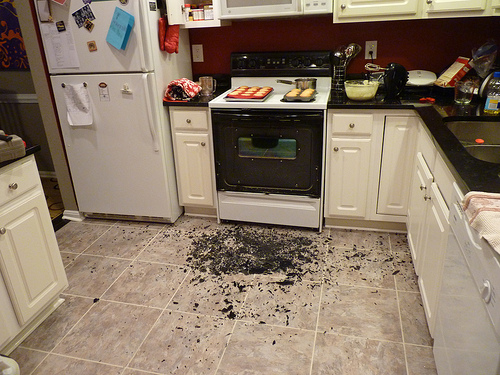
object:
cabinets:
[329, 0, 495, 24]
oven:
[210, 108, 324, 199]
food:
[227, 81, 317, 101]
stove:
[207, 76, 328, 108]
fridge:
[32, 1, 186, 223]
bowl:
[344, 80, 380, 101]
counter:
[327, 76, 449, 109]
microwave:
[210, 0, 339, 20]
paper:
[104, 6, 137, 51]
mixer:
[364, 62, 409, 102]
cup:
[454, 82, 475, 105]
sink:
[444, 118, 500, 169]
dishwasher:
[429, 197, 500, 374]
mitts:
[159, 16, 183, 54]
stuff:
[66, 215, 439, 374]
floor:
[3, 219, 442, 375]